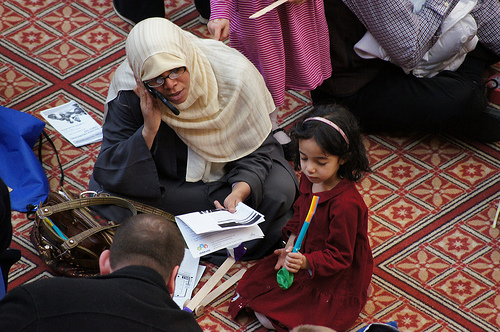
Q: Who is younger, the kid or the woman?
A: The kid is younger than the woman.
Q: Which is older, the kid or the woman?
A: The woman is older than the kid.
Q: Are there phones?
A: Yes, there is a phone.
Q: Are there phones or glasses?
A: Yes, there is a phone.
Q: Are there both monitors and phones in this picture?
A: No, there is a phone but no monitors.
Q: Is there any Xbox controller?
A: No, there are no Xbox controllers.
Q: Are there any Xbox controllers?
A: No, there are no Xbox controllers.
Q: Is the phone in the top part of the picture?
A: Yes, the phone is in the top of the image.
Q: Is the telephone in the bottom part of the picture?
A: No, the telephone is in the top of the image.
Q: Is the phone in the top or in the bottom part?
A: The phone is in the top of the image.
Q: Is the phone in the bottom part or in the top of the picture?
A: The phone is in the top of the image.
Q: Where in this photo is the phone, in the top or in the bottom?
A: The phone is in the top of the image.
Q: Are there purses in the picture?
A: Yes, there is a purse.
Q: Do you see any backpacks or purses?
A: Yes, there is a purse.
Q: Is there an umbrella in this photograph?
A: No, there are no umbrellas.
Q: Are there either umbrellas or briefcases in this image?
A: No, there are no umbrellas or briefcases.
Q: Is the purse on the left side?
A: Yes, the purse is on the left of the image.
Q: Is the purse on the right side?
A: No, the purse is on the left of the image.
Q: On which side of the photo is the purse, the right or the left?
A: The purse is on the left of the image.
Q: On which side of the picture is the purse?
A: The purse is on the left of the image.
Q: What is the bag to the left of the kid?
A: The bag is a purse.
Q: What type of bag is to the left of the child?
A: The bag is a purse.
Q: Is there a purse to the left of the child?
A: Yes, there is a purse to the left of the child.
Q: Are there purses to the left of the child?
A: Yes, there is a purse to the left of the child.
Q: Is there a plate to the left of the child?
A: No, there is a purse to the left of the child.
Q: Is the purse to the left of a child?
A: Yes, the purse is to the left of a child.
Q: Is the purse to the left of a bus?
A: No, the purse is to the left of a child.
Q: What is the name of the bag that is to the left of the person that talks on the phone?
A: The bag is a purse.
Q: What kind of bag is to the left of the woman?
A: The bag is a purse.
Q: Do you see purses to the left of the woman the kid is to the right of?
A: Yes, there is a purse to the left of the woman.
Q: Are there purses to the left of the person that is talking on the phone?
A: Yes, there is a purse to the left of the woman.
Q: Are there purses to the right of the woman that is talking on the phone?
A: No, the purse is to the left of the woman.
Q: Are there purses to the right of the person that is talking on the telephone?
A: No, the purse is to the left of the woman.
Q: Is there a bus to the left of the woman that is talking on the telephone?
A: No, there is a purse to the left of the woman.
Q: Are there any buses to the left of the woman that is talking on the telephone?
A: No, there is a purse to the left of the woman.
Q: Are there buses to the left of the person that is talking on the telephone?
A: No, there is a purse to the left of the woman.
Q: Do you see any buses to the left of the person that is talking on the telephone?
A: No, there is a purse to the left of the woman.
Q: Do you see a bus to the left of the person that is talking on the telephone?
A: No, there is a purse to the left of the woman.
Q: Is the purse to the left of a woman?
A: Yes, the purse is to the left of a woman.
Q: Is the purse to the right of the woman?
A: No, the purse is to the left of the woman.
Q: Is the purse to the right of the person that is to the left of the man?
A: No, the purse is to the left of the woman.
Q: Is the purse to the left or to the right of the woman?
A: The purse is to the left of the woman.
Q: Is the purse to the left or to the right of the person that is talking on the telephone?
A: The purse is to the left of the woman.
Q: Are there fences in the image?
A: No, there are no fences.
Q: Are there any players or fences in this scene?
A: No, there are no fences or players.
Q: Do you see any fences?
A: No, there are no fences.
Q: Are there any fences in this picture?
A: No, there are no fences.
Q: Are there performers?
A: No, there are no performers.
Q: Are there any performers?
A: No, there are no performers.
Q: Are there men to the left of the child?
A: Yes, there is a man to the left of the child.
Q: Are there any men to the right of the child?
A: No, the man is to the left of the child.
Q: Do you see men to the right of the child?
A: No, the man is to the left of the child.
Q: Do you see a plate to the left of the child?
A: No, there is a man to the left of the child.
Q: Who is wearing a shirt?
A: The man is wearing a shirt.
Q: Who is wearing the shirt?
A: The man is wearing a shirt.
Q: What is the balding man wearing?
A: The man is wearing a shirt.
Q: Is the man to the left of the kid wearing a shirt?
A: Yes, the man is wearing a shirt.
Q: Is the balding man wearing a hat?
A: No, the man is wearing a shirt.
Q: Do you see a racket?
A: No, there are no rackets.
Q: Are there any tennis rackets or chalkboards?
A: No, there are no tennis rackets or chalkboards.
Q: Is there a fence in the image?
A: No, there are no fences.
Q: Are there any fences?
A: No, there are no fences.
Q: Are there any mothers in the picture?
A: No, there are no mothers.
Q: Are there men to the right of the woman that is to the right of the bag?
A: Yes, there is a man to the right of the woman.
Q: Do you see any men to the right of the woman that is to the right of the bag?
A: Yes, there is a man to the right of the woman.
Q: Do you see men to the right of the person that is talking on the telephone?
A: Yes, there is a man to the right of the woman.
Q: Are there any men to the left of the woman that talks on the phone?
A: No, the man is to the right of the woman.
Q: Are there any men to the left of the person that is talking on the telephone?
A: No, the man is to the right of the woman.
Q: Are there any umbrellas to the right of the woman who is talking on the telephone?
A: No, there is a man to the right of the woman.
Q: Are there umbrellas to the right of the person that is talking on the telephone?
A: No, there is a man to the right of the woman.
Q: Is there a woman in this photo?
A: Yes, there is a woman.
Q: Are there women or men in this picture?
A: Yes, there is a woman.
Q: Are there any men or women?
A: Yes, there is a woman.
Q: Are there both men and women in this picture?
A: Yes, there are both a woman and a man.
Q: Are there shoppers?
A: No, there are no shoppers.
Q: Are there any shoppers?
A: No, there are no shoppers.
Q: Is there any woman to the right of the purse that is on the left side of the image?
A: Yes, there is a woman to the right of the purse.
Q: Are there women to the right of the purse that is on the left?
A: Yes, there is a woman to the right of the purse.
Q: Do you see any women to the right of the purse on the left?
A: Yes, there is a woman to the right of the purse.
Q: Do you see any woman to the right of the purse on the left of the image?
A: Yes, there is a woman to the right of the purse.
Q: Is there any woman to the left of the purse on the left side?
A: No, the woman is to the right of the purse.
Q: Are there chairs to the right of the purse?
A: No, there is a woman to the right of the purse.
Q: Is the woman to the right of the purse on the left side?
A: Yes, the woman is to the right of the purse.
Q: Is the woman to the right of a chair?
A: No, the woman is to the right of the purse.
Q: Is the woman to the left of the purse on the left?
A: No, the woman is to the right of the purse.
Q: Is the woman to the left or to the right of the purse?
A: The woman is to the right of the purse.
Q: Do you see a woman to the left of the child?
A: Yes, there is a woman to the left of the child.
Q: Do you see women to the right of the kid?
A: No, the woman is to the left of the kid.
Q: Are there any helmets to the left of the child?
A: No, there is a woman to the left of the child.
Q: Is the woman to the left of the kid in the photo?
A: Yes, the woman is to the left of the kid.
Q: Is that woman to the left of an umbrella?
A: No, the woman is to the left of the kid.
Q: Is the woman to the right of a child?
A: No, the woman is to the left of a child.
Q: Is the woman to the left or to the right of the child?
A: The woman is to the left of the child.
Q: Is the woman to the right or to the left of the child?
A: The woman is to the left of the child.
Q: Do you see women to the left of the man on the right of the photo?
A: Yes, there is a woman to the left of the man.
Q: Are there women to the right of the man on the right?
A: No, the woman is to the left of the man.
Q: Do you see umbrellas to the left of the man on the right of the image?
A: No, there is a woman to the left of the man.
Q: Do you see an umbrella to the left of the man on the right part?
A: No, there is a woman to the left of the man.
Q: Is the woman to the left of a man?
A: Yes, the woman is to the left of a man.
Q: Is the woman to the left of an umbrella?
A: No, the woman is to the left of a man.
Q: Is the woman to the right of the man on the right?
A: No, the woman is to the left of the man.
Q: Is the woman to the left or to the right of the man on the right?
A: The woman is to the left of the man.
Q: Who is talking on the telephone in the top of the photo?
A: The woman is talking on the phone.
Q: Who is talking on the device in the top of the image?
A: The woman is talking on the phone.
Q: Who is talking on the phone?
A: The woman is talking on the phone.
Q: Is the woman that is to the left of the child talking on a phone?
A: Yes, the woman is talking on a phone.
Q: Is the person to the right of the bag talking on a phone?
A: Yes, the woman is talking on a phone.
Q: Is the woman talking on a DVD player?
A: No, the woman is talking on a phone.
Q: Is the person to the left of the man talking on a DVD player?
A: No, the woman is talking on a phone.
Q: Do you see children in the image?
A: Yes, there is a child.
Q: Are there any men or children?
A: Yes, there is a child.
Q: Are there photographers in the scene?
A: No, there are no photographers.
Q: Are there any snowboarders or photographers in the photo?
A: No, there are no photographers or snowboarders.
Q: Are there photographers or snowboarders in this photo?
A: No, there are no photographers or snowboarders.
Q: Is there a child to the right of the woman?
A: Yes, there is a child to the right of the woman.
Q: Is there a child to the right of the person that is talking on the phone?
A: Yes, there is a child to the right of the woman.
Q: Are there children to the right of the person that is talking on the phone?
A: Yes, there is a child to the right of the woman.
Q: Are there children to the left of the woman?
A: No, the child is to the right of the woman.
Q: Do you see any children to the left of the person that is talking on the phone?
A: No, the child is to the right of the woman.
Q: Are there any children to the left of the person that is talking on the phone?
A: No, the child is to the right of the woman.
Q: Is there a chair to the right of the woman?
A: No, there is a child to the right of the woman.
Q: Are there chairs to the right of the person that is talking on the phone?
A: No, there is a child to the right of the woman.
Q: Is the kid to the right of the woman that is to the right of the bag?
A: Yes, the kid is to the right of the woman.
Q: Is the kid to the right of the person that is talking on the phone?
A: Yes, the kid is to the right of the woman.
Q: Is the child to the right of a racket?
A: No, the child is to the right of the woman.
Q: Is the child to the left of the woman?
A: No, the child is to the right of the woman.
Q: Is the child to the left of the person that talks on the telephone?
A: No, the child is to the right of the woman.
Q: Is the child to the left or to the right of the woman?
A: The child is to the right of the woman.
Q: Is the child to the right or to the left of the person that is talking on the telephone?
A: The child is to the right of the woman.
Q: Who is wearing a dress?
A: The child is wearing a dress.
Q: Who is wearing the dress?
A: The child is wearing a dress.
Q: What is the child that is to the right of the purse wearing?
A: The child is wearing a dress.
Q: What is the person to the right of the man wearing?
A: The child is wearing a dress.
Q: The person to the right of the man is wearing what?
A: The child is wearing a dress.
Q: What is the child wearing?
A: The child is wearing a dress.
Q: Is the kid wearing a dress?
A: Yes, the kid is wearing a dress.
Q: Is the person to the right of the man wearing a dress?
A: Yes, the kid is wearing a dress.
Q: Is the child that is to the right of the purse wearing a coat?
A: No, the kid is wearing a dress.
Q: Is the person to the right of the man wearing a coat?
A: No, the kid is wearing a dress.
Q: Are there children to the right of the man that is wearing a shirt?
A: Yes, there is a child to the right of the man.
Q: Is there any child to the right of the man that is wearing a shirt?
A: Yes, there is a child to the right of the man.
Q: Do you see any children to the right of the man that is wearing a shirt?
A: Yes, there is a child to the right of the man.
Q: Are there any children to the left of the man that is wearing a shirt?
A: No, the child is to the right of the man.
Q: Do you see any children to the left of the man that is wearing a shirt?
A: No, the child is to the right of the man.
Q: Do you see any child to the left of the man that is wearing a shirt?
A: No, the child is to the right of the man.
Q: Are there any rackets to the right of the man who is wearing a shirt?
A: No, there is a child to the right of the man.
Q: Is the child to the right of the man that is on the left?
A: Yes, the child is to the right of the man.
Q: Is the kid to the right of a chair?
A: No, the kid is to the right of the man.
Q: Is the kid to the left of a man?
A: No, the kid is to the right of a man.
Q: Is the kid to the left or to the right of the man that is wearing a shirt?
A: The kid is to the right of the man.